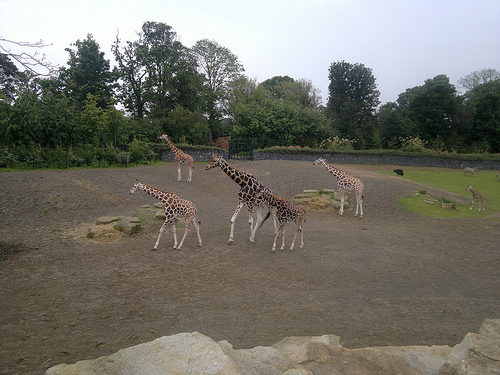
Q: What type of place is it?
A: It is a pen.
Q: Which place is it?
A: It is a pen.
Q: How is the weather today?
A: It is cloudy.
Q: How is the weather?
A: It is cloudy.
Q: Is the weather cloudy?
A: Yes, it is cloudy.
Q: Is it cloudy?
A: Yes, it is cloudy.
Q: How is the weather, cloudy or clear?
A: It is cloudy.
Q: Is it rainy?
A: No, it is cloudy.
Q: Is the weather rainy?
A: No, it is cloudy.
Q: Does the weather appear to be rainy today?
A: No, it is cloudy.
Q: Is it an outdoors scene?
A: Yes, it is outdoors.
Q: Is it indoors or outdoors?
A: It is outdoors.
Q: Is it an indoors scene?
A: No, it is outdoors.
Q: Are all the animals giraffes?
A: No, there are both giraffes and birds.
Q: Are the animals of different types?
A: Yes, they are giraffes and birds.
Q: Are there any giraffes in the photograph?
A: Yes, there is a giraffe.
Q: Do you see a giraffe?
A: Yes, there is a giraffe.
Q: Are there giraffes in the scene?
A: Yes, there is a giraffe.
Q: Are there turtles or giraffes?
A: Yes, there is a giraffe.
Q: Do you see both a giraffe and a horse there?
A: No, there is a giraffe but no horses.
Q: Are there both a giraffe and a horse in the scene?
A: No, there is a giraffe but no horses.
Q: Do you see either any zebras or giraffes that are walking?
A: Yes, the giraffe is walking.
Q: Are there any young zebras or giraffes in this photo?
A: Yes, there is a young giraffe.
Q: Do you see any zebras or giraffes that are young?
A: Yes, the giraffe is young.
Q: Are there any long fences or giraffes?
A: Yes, there is a long giraffe.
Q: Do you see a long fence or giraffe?
A: Yes, there is a long giraffe.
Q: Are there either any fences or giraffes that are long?
A: Yes, the giraffe is long.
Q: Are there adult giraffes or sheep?
A: Yes, there is an adult giraffe.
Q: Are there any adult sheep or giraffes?
A: Yes, there is an adult giraffe.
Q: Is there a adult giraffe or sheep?
A: Yes, there is an adult giraffe.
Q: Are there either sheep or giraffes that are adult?
A: Yes, the giraffe is adult.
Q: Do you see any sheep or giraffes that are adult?
A: Yes, the giraffe is adult.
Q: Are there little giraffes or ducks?
A: Yes, there is a little giraffe.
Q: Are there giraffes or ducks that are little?
A: Yes, the giraffe is little.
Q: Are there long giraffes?
A: Yes, there is a long giraffe.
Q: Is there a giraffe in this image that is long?
A: Yes, there is a giraffe that is long.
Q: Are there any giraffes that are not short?
A: Yes, there is a long giraffe.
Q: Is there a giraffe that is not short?
A: Yes, there is a long giraffe.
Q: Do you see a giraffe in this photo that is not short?
A: Yes, there is a long giraffe.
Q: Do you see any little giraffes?
A: Yes, there is a little giraffe.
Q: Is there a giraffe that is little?
A: Yes, there is a giraffe that is little.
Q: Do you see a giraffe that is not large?
A: Yes, there is a little giraffe.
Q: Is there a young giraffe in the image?
A: Yes, there is a young giraffe.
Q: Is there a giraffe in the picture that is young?
A: Yes, there is a giraffe that is young.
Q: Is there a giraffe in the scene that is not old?
A: Yes, there is an young giraffe.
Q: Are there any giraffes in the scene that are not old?
A: Yes, there is an young giraffe.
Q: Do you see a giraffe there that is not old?
A: Yes, there is an young giraffe.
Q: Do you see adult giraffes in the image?
A: Yes, there is an adult giraffe.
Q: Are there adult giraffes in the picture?
A: Yes, there is an adult giraffe.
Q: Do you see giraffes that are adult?
A: Yes, there is a giraffe that is adult.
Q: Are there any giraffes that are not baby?
A: Yes, there is a adult giraffe.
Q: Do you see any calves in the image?
A: No, there are no calves.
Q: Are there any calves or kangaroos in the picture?
A: No, there are no calves or kangaroos.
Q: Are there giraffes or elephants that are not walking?
A: No, there is a giraffe but it is walking.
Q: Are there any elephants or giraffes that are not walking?
A: No, there is a giraffe but it is walking.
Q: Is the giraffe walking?
A: Yes, the giraffe is walking.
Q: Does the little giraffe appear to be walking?
A: Yes, the giraffe is walking.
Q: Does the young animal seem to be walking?
A: Yes, the giraffe is walking.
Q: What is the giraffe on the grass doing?
A: The giraffe is walking.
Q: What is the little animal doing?
A: The giraffe is walking.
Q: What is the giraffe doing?
A: The giraffe is walking.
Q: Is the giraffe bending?
A: No, the giraffe is walking.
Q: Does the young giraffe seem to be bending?
A: No, the giraffe is walking.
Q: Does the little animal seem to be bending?
A: No, the giraffe is walking.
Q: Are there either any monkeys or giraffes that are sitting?
A: No, there is a giraffe but it is walking.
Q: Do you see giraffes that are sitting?
A: No, there is a giraffe but it is walking.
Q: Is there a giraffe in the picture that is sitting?
A: No, there is a giraffe but it is walking.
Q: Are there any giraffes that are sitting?
A: No, there is a giraffe but it is walking.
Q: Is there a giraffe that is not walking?
A: No, there is a giraffe but it is walking.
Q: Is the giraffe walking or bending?
A: The giraffe is walking.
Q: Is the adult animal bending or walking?
A: The giraffe is walking.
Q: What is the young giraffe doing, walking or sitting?
A: The giraffe is walking.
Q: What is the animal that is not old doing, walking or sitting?
A: The giraffe is walking.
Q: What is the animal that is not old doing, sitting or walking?
A: The giraffe is walking.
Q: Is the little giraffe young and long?
A: Yes, the giraffe is young and long.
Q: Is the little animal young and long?
A: Yes, the giraffe is young and long.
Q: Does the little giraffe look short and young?
A: No, the giraffe is young but long.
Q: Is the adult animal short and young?
A: No, the giraffe is young but long.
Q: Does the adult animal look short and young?
A: No, the giraffe is young but long.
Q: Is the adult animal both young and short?
A: No, the giraffe is young but long.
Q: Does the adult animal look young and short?
A: No, the giraffe is young but long.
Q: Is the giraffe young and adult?
A: Yes, the giraffe is young and adult.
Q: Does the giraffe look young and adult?
A: Yes, the giraffe is young and adult.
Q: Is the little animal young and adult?
A: Yes, the giraffe is young and adult.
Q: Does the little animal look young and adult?
A: Yes, the giraffe is young and adult.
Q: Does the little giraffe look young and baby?
A: No, the giraffe is young but adult.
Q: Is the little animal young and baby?
A: No, the giraffe is young but adult.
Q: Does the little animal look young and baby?
A: No, the giraffe is young but adult.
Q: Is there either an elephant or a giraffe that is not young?
A: No, there is a giraffe but it is young.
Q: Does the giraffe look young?
A: Yes, the giraffe is young.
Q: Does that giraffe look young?
A: Yes, the giraffe is young.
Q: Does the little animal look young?
A: Yes, the giraffe is young.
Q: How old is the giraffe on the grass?
A: The giraffe is young.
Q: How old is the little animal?
A: The giraffe is young.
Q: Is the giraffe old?
A: No, the giraffe is young.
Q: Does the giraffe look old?
A: No, the giraffe is young.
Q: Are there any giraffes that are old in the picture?
A: No, there is a giraffe but it is young.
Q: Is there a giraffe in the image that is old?
A: No, there is a giraffe but it is young.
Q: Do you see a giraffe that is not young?
A: No, there is a giraffe but it is young.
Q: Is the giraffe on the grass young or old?
A: The giraffe is young.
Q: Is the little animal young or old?
A: The giraffe is young.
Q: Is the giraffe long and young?
A: Yes, the giraffe is long and young.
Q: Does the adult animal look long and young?
A: Yes, the giraffe is long and young.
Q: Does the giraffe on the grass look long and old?
A: No, the giraffe is long but young.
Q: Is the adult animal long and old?
A: No, the giraffe is long but young.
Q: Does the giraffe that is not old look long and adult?
A: Yes, the giraffe is long and adult.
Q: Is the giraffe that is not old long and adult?
A: Yes, the giraffe is long and adult.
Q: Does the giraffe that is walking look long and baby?
A: No, the giraffe is long but adult.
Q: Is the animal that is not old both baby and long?
A: No, the giraffe is long but adult.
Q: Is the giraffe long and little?
A: Yes, the giraffe is long and little.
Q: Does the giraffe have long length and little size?
A: Yes, the giraffe is long and little.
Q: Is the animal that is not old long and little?
A: Yes, the giraffe is long and little.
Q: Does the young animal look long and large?
A: No, the giraffe is long but little.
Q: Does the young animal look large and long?
A: No, the giraffe is long but little.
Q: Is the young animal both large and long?
A: No, the giraffe is long but little.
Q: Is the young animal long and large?
A: No, the giraffe is long but little.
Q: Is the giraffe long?
A: Yes, the giraffe is long.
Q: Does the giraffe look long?
A: Yes, the giraffe is long.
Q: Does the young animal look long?
A: Yes, the giraffe is long.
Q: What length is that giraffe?
A: The giraffe is long.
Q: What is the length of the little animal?
A: The giraffe is long.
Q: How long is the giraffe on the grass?
A: The giraffe is long.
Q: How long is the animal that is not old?
A: The giraffe is long.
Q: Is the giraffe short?
A: No, the giraffe is long.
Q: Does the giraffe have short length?
A: No, the giraffe is long.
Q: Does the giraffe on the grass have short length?
A: No, the giraffe is long.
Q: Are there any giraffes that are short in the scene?
A: No, there is a giraffe but it is long.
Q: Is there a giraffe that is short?
A: No, there is a giraffe but it is long.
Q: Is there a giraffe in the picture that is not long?
A: No, there is a giraffe but it is long.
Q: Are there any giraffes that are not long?
A: No, there is a giraffe but it is long.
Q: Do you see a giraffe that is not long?
A: No, there is a giraffe but it is long.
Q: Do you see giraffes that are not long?
A: No, there is a giraffe but it is long.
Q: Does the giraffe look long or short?
A: The giraffe is long.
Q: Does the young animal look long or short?
A: The giraffe is long.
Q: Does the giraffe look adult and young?
A: Yes, the giraffe is adult and young.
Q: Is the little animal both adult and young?
A: Yes, the giraffe is adult and young.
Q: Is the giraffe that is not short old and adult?
A: No, the giraffe is adult but young.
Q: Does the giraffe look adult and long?
A: Yes, the giraffe is adult and long.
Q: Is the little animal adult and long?
A: Yes, the giraffe is adult and long.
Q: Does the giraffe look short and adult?
A: No, the giraffe is adult but long.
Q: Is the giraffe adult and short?
A: No, the giraffe is adult but long.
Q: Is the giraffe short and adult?
A: No, the giraffe is adult but long.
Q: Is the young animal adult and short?
A: No, the giraffe is adult but long.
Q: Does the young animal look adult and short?
A: No, the giraffe is adult but long.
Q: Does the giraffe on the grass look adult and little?
A: Yes, the giraffe is adult and little.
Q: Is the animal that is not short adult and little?
A: Yes, the giraffe is adult and little.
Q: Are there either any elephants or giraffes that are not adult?
A: No, there is a giraffe but it is adult.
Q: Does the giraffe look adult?
A: Yes, the giraffe is adult.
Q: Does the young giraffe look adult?
A: Yes, the giraffe is adult.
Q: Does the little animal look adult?
A: Yes, the giraffe is adult.